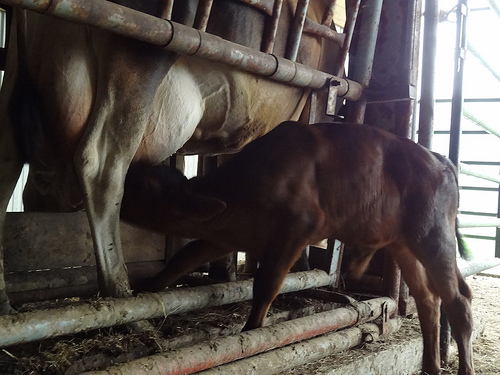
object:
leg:
[417, 232, 472, 374]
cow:
[119, 120, 477, 375]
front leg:
[239, 225, 305, 346]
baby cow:
[109, 120, 476, 139]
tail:
[439, 151, 472, 262]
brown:
[190, 30, 295, 88]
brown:
[303, 138, 388, 227]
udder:
[133, 68, 203, 164]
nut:
[329, 79, 343, 91]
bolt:
[327, 74, 338, 88]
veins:
[217, 75, 237, 132]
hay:
[100, 327, 124, 360]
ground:
[0, 291, 500, 374]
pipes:
[2, 270, 400, 371]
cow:
[0, 29, 352, 338]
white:
[149, 100, 190, 136]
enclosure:
[0, 2, 393, 114]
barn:
[0, 2, 499, 86]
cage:
[0, 0, 386, 102]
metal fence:
[413, 0, 498, 285]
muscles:
[319, 135, 386, 216]